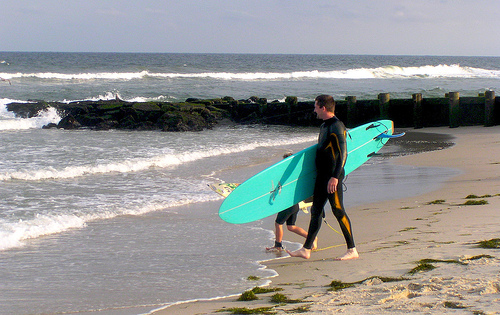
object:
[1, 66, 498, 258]
waves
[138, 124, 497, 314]
beach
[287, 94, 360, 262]
man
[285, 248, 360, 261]
feet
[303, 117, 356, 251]
wet suit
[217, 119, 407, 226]
surfboard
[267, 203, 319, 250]
child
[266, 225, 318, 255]
legs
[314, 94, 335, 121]
head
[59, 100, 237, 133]
rocks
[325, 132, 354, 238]
design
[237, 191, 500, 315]
seaweed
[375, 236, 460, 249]
tracks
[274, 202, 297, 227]
shorts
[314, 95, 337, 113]
hair